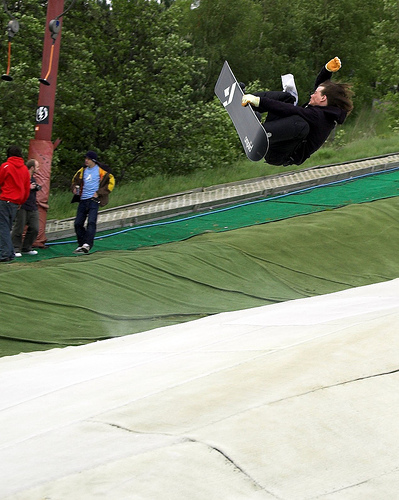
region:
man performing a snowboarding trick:
[211, 46, 353, 168]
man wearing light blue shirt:
[64, 147, 113, 250]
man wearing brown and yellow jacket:
[66, 150, 114, 203]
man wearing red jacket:
[0, 141, 27, 201]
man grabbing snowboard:
[199, 46, 342, 158]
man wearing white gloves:
[201, 39, 340, 159]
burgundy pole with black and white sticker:
[16, 0, 58, 234]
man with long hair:
[219, 53, 353, 172]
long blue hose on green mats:
[108, 167, 395, 250]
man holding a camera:
[24, 157, 42, 249]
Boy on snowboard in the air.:
[216, 40, 353, 165]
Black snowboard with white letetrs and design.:
[210, 59, 270, 162]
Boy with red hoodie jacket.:
[0, 141, 27, 262]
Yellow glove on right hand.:
[322, 49, 341, 74]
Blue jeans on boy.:
[65, 202, 98, 249]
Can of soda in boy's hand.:
[70, 183, 81, 195]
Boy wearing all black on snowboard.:
[208, 56, 352, 165]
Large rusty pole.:
[37, 3, 58, 247]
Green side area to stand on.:
[3, 219, 398, 307]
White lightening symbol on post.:
[31, 104, 53, 123]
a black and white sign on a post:
[34, 102, 49, 124]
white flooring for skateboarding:
[80, 341, 337, 489]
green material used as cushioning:
[72, 260, 195, 298]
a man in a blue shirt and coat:
[78, 149, 108, 252]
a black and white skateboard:
[218, 78, 263, 161]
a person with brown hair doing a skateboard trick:
[262, 53, 361, 184]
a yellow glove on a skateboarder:
[326, 59, 340, 72]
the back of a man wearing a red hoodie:
[5, 148, 23, 258]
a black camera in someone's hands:
[31, 180, 45, 192]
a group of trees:
[87, 15, 208, 142]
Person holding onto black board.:
[204, 64, 293, 183]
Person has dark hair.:
[320, 76, 366, 150]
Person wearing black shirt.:
[278, 93, 339, 160]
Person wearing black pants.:
[247, 89, 292, 191]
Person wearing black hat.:
[80, 151, 114, 176]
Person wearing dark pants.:
[58, 207, 133, 260]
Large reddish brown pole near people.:
[20, 97, 58, 240]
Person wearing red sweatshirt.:
[16, 157, 25, 211]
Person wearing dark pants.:
[15, 213, 52, 253]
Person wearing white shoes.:
[13, 241, 32, 255]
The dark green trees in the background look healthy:
[123, 42, 185, 191]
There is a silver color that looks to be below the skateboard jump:
[229, 428, 254, 469]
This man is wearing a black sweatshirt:
[220, 8, 339, 173]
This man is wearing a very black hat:
[77, 148, 101, 258]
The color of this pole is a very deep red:
[39, 45, 60, 92]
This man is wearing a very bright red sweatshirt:
[8, 142, 22, 251]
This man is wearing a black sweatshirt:
[24, 158, 39, 265]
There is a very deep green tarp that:
[302, 227, 325, 267]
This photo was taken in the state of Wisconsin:
[137, 37, 289, 330]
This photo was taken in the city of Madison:
[92, 33, 301, 292]